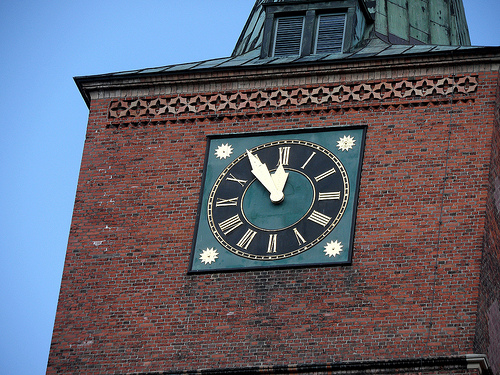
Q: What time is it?
A: 11:55.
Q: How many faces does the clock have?
A: 1.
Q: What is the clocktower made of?
A: Brick.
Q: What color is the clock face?
A: Blue.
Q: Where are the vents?
A: Above the clock.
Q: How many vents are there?
A: 2.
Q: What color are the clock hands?
A: Gold.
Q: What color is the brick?
A: Red.